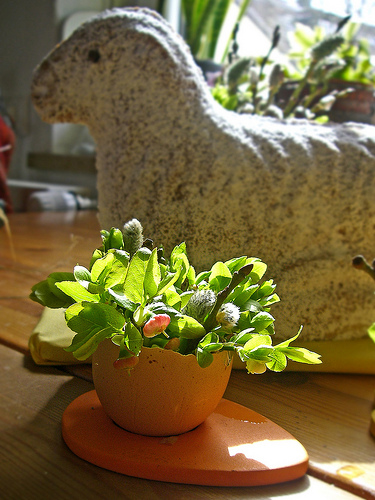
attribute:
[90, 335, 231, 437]
planter — red clay flower pot, ceramic pot, red pot, upon floor, egg-like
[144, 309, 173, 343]
red blossom — single pink flower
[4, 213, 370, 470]
table — made of wood, wooden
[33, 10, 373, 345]
sheep — large, fake, stone toy, ornamental, made of porcelain, on floor, made of cement, made from concrete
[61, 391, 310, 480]
base — orange, made of clay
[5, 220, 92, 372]
counter — shiny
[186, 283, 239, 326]
flower buds — green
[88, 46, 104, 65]
eye — black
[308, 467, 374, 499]
split — on wood surface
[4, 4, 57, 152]
wall — painted grey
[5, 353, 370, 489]
floor — hardwood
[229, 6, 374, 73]
window — behind sheep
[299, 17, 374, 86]
plant — leafy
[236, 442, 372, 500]
light — reflecting on wood